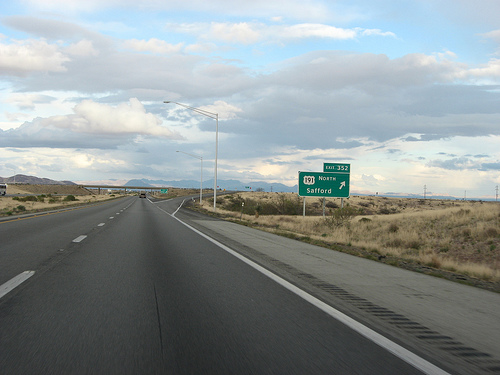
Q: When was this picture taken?
A: During the day.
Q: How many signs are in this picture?
A: One.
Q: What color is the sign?
A: Green.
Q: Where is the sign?
A: Next to the road.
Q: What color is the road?
A: Black.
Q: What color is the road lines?
A: White.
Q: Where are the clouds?
A: In the sky.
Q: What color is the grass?
A: Brown.